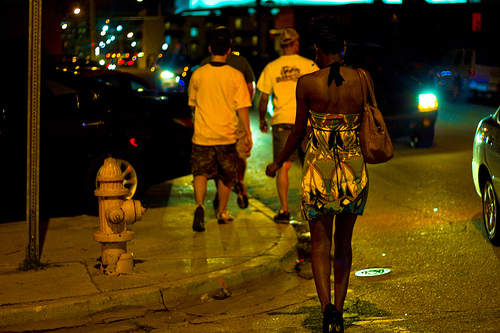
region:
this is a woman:
[270, 21, 413, 331]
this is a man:
[163, 22, 277, 265]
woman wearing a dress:
[270, 10, 425, 260]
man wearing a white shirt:
[173, 51, 265, 153]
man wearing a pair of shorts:
[178, 114, 251, 211]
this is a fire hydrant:
[66, 132, 174, 304]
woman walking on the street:
[263, 15, 411, 316]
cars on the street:
[252, 16, 499, 236]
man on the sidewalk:
[140, 11, 290, 311]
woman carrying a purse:
[349, 67, 425, 202]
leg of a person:
[296, 218, 337, 322]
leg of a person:
[326, 220, 368, 302]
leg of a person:
[257, 162, 297, 237]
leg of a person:
[174, 175, 211, 249]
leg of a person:
[208, 153, 245, 233]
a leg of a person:
[285, 210, 335, 322]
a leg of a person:
[319, 219, 379, 322]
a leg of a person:
[166, 162, 211, 259]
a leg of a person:
[208, 156, 253, 227]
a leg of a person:
[255, 158, 306, 242]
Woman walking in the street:
[273, 28, 405, 332]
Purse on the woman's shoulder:
[345, 60, 400, 167]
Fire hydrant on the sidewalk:
[77, 151, 152, 279]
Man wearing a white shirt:
[243, 21, 350, 224]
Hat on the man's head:
[269, 20, 305, 49]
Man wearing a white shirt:
[177, 27, 258, 237]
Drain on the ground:
[343, 251, 413, 292]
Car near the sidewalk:
[0, 60, 197, 224]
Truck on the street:
[262, 5, 467, 166]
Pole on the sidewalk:
[11, 0, 66, 282]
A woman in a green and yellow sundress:
[296, 28, 392, 330]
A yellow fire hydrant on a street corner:
[81, 148, 149, 275]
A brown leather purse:
[359, 104, 393, 163]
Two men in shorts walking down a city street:
[181, 23, 322, 235]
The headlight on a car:
[354, 65, 441, 150]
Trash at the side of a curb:
[199, 280, 232, 305]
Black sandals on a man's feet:
[188, 196, 236, 233]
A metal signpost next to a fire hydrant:
[20, 1, 51, 268]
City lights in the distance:
[56, 6, 144, 83]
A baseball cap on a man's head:
[273, 24, 301, 51]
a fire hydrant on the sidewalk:
[69, 119, 195, 316]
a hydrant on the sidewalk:
[82, 156, 147, 281]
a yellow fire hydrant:
[93, 149, 169, 293]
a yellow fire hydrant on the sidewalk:
[72, 138, 169, 311]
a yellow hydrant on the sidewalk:
[54, 143, 264, 331]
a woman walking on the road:
[260, 27, 440, 330]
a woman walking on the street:
[264, 59, 429, 331]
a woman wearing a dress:
[273, 75, 443, 327]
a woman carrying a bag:
[272, 39, 429, 256]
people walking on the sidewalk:
[139, 39, 417, 281]